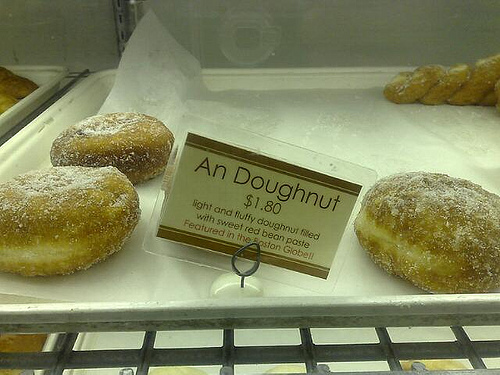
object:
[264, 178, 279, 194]
letter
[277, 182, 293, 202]
letter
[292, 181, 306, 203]
letter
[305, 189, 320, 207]
letter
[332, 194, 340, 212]
letter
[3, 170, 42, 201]
powder sugar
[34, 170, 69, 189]
powder sugar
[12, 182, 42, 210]
powder sugar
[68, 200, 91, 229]
powder sugar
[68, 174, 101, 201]
powder sugar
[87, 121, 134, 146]
powder sugar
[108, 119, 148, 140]
powder sugar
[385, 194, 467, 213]
powder sugar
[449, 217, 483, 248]
powder sugar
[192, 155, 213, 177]
letter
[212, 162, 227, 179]
letter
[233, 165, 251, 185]
letter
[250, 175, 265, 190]
letter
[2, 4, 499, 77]
wall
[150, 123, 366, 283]
tag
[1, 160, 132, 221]
sprinkles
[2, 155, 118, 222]
topping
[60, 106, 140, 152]
topping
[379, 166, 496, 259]
topping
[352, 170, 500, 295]
donut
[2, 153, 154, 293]
donut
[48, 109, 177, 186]
donut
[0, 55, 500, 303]
paper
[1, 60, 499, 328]
tray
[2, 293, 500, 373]
stand